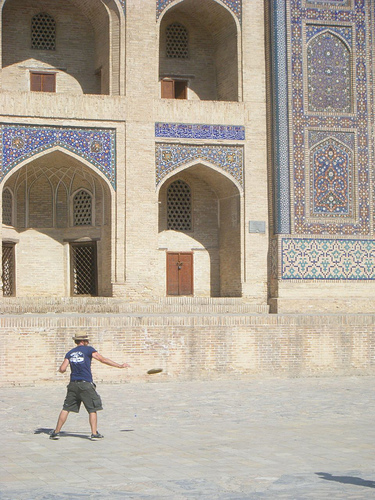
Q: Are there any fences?
A: No, there are no fences.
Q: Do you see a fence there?
A: No, there are no fences.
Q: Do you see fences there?
A: No, there are no fences.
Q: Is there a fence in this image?
A: No, there are no fences.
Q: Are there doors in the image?
A: Yes, there is a door.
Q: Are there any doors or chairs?
A: Yes, there is a door.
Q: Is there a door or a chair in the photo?
A: Yes, there is a door.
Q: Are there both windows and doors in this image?
A: Yes, there are both a door and a window.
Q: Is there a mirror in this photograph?
A: No, there are no mirrors.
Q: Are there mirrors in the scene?
A: No, there are no mirrors.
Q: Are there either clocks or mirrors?
A: No, there are no mirrors or clocks.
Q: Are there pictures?
A: No, there are no pictures.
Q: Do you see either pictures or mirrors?
A: No, there are no pictures or mirrors.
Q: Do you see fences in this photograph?
A: No, there are no fences.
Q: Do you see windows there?
A: Yes, there is a window.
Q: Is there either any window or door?
A: Yes, there is a window.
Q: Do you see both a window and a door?
A: Yes, there are both a window and a door.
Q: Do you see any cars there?
A: No, there are no cars.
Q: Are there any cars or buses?
A: No, there are no cars or buses.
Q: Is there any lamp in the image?
A: No, there are no lamps.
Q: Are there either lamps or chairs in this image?
A: No, there are no lamps or chairs.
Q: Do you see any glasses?
A: No, there are no glasses.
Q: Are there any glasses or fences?
A: No, there are no glasses or fences.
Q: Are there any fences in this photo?
A: No, there are no fences.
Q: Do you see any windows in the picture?
A: Yes, there is a window.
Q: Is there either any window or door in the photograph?
A: Yes, there is a window.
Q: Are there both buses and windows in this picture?
A: No, there is a window but no buses.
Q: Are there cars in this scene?
A: No, there are no cars.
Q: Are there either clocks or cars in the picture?
A: No, there are no cars or clocks.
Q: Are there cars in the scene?
A: No, there are no cars.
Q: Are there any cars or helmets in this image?
A: No, there are no cars or helmets.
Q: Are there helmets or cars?
A: No, there are no cars or helmets.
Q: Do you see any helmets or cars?
A: No, there are no cars or helmets.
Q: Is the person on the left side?
A: Yes, the person is on the left of the image.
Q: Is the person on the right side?
A: No, the person is on the left of the image.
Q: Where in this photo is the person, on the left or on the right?
A: The person is on the left of the image.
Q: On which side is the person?
A: The person is on the left of the image.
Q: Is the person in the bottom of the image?
A: Yes, the person is in the bottom of the image.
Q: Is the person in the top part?
A: No, the person is in the bottom of the image.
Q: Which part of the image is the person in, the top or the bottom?
A: The person is in the bottom of the image.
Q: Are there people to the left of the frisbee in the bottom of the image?
A: Yes, there is a person to the left of the frisbee.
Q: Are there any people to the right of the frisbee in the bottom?
A: No, the person is to the left of the frisbee.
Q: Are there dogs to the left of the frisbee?
A: No, there is a person to the left of the frisbee.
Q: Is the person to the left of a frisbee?
A: Yes, the person is to the left of a frisbee.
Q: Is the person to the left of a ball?
A: No, the person is to the left of a frisbee.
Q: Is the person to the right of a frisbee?
A: No, the person is to the left of a frisbee.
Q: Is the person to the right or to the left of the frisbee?
A: The person is to the left of the frisbee.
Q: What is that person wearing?
A: The person is wearing trousers.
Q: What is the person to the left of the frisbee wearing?
A: The person is wearing trousers.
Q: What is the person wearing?
A: The person is wearing trousers.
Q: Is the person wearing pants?
A: Yes, the person is wearing pants.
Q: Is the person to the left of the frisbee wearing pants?
A: Yes, the person is wearing pants.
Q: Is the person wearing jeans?
A: No, the person is wearing pants.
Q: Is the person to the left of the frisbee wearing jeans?
A: No, the person is wearing pants.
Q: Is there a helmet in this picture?
A: No, there are no helmets.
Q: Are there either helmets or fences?
A: No, there are no helmets or fences.